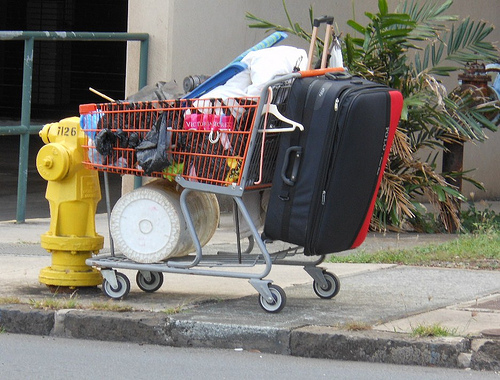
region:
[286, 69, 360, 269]
Blue suitcase on back of shopping cart.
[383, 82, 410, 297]
Red marking on side of suitcase.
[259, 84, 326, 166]
White hanger hanging on shopping cart.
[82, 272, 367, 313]
Black wheels on shopping cart.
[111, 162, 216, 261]
White bucket on bottom of shopping cart.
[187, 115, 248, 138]
Victoria's Secret bag inside of shopping cart.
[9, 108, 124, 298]
Yellow fire hydrant on sidewalk.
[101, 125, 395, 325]
Shopping cart near fire hydrant on sidewalk.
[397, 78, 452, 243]
Green and brown leaves on plant in background.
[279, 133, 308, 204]
Blue handle on suitcase.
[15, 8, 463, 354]
a cart next to a fire hydrant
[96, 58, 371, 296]
this cart is loaded with stuff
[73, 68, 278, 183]
there are clothes in this cart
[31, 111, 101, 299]
a yellow fire hydrant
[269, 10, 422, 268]
a black and red suitcase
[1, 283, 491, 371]
a curb on the steet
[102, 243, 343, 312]
wheels on a cart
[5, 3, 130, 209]
an entrance way to a building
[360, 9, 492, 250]
shrubbery near the cart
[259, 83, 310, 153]
a hanger by the suitcase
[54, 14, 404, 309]
a full shopping cart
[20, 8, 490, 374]
the cart is on the sidewalk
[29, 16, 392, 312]
the cart is by a fire hydrant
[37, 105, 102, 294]
the fire hydrant is yellow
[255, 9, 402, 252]
a suitcase hooked on the end of the cart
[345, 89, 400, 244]
the suitcase trim is red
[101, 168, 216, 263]
a bucket on the bottom of the cart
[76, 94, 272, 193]
the cart bed is red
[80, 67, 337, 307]
the cart frame is silver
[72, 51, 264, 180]
the cart bed is full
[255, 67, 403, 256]
blue and red suitcase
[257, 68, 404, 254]
blue suitcase with red stripe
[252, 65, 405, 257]
blue suitcase hanging on a grocery cart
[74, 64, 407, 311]
red and gray grocery card against a hydrant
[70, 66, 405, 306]
grocery cart with suitcase hanging on it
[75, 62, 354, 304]
red and gray grocery cart with persons belongings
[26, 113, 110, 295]
yellow fire hydrant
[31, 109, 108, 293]
yellow fire hydrant next to grocery cart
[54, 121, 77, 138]
numbers on the fire hydrant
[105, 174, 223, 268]
white bucket on lower shelf of buggy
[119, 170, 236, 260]
white bucket under cart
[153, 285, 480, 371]
gray colored curb side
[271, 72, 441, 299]
black and red suitcase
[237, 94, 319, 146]
white hanger hanging from cart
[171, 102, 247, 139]
victoria secret bag in cart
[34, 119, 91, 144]
the number "7126" on hydrant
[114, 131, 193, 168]
a small black plastic bag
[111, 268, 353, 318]
four wheels on the cart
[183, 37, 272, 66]
a blue and green lawn chair